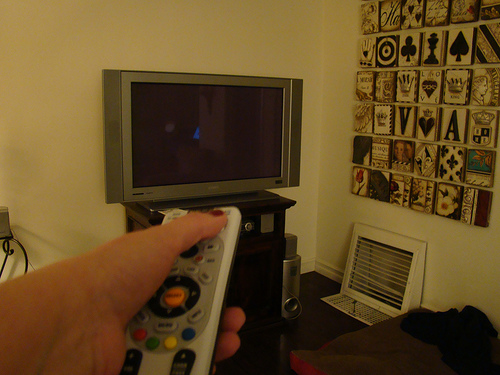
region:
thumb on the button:
[198, 206, 239, 236]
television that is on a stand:
[93, 66, 318, 213]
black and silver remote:
[97, 196, 229, 372]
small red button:
[129, 323, 144, 343]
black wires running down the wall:
[1, 238, 43, 290]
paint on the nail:
[203, 205, 225, 223]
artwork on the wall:
[332, 3, 499, 230]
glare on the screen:
[190, 126, 208, 142]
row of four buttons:
[129, 326, 204, 355]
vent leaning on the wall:
[330, 224, 442, 331]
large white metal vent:
[327, 222, 419, 329]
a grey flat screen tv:
[101, 68, 308, 209]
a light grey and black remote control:
[118, 206, 248, 373]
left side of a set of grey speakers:
[282, 235, 302, 325]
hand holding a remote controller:
[1, 195, 242, 370]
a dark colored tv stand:
[121, 191, 280, 359]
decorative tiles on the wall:
[351, 5, 499, 227]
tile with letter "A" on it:
[440, 105, 468, 144]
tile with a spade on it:
[448, 23, 475, 65]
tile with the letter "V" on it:
[392, 104, 415, 138]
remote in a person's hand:
[126, 203, 241, 373]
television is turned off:
[103, 66, 301, 198]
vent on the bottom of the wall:
[346, 213, 429, 315]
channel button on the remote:
[171, 346, 197, 373]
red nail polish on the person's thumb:
[210, 205, 227, 215]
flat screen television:
[99, 62, 303, 207]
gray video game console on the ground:
[277, 228, 301, 318]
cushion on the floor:
[286, 290, 488, 373]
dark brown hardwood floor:
[274, 265, 375, 346]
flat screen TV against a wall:
[87, 58, 312, 208]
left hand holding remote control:
[49, 209, 253, 374]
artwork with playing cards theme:
[350, 5, 498, 216]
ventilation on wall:
[328, 214, 427, 321]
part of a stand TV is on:
[240, 199, 287, 338]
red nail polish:
[199, 200, 231, 222]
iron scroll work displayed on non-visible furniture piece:
[1, 232, 30, 272]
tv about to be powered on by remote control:
[70, 50, 313, 372]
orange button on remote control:
[162, 285, 188, 309]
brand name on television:
[125, 187, 162, 202]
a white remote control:
[119, 201, 244, 371]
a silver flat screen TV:
[99, 68, 303, 204]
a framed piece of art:
[346, 164, 370, 199]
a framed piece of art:
[364, 168, 390, 203]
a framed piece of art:
[384, 170, 412, 208]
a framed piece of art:
[407, 175, 436, 214]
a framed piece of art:
[433, 180, 463, 220]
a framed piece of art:
[458, 183, 495, 230]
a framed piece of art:
[463, 145, 495, 187]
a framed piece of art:
[435, 141, 469, 184]